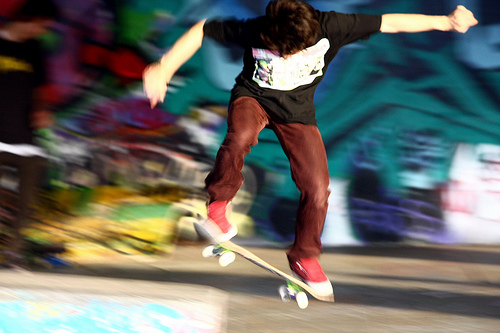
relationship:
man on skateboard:
[126, 0, 480, 299] [178, 219, 347, 310]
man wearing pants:
[126, 0, 480, 299] [209, 89, 334, 263]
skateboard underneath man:
[178, 219, 347, 310] [126, 0, 480, 299]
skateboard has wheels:
[178, 219, 347, 310] [193, 240, 313, 308]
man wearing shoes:
[126, 0, 480, 299] [197, 197, 344, 290]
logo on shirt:
[252, 42, 324, 89] [209, 15, 351, 126]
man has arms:
[126, 0, 480, 299] [163, 10, 454, 78]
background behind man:
[1, 1, 496, 266] [126, 0, 480, 299]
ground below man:
[4, 243, 499, 330] [126, 0, 480, 299]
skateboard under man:
[178, 219, 347, 310] [126, 0, 480, 299]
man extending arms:
[126, 0, 480, 299] [163, 10, 454, 78]